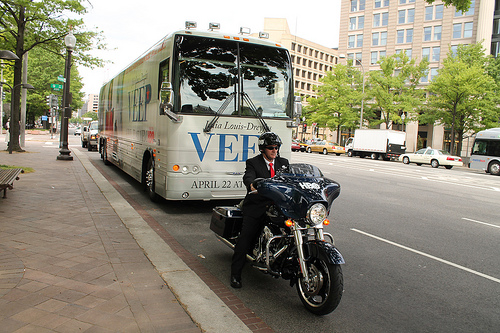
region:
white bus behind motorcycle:
[99, 24, 294, 205]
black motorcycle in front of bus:
[209, 161, 347, 314]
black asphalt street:
[67, 130, 498, 327]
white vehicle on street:
[398, 145, 464, 169]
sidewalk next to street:
[2, 140, 252, 327]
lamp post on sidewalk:
[54, 32, 78, 163]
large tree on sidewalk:
[2, 0, 109, 156]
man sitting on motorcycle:
[227, 132, 293, 286]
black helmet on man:
[257, 129, 280, 161]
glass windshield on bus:
[172, 27, 296, 122]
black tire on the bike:
[282, 225, 353, 328]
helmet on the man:
[243, 123, 298, 173]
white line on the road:
[333, 198, 466, 318]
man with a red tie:
[225, 125, 309, 230]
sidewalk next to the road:
[28, 205, 95, 308]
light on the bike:
[288, 192, 345, 243]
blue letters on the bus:
[173, 122, 253, 182]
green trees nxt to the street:
[292, 16, 479, 137]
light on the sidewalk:
[38, 28, 91, 160]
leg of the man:
[209, 230, 262, 298]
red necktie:
[257, 157, 317, 204]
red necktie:
[259, 150, 296, 193]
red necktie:
[261, 154, 284, 186]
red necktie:
[264, 157, 284, 174]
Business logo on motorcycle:
[293, 175, 325, 197]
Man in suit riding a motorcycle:
[192, 123, 367, 323]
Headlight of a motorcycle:
[300, 196, 334, 233]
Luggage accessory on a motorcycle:
[207, 197, 249, 242]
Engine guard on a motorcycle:
[257, 231, 339, 276]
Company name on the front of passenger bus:
[185, 123, 287, 169]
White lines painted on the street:
[355, 222, 455, 276]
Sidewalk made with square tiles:
[42, 186, 94, 318]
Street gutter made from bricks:
[152, 214, 203, 266]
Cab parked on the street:
[398, 136, 463, 180]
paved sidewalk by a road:
[33, 188, 156, 325]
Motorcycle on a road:
[212, 163, 352, 331]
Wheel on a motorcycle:
[288, 233, 343, 328]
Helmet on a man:
[256, 129, 291, 170]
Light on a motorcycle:
[298, 189, 329, 226]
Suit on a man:
[243, 150, 307, 261]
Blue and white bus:
[93, 16, 325, 228]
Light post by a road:
[53, 20, 104, 184]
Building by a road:
[336, 3, 482, 179]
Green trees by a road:
[305, 56, 487, 166]